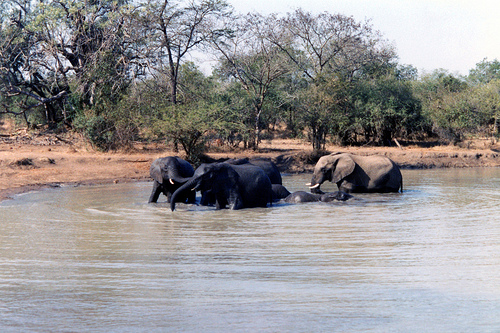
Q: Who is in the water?
A: Elephants.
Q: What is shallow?
A: Water.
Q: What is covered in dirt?
A: The ground.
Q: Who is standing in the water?
A: A elephant.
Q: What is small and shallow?
A: A pond.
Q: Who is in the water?
A: Elephants.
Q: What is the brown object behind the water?
A: Land.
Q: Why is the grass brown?
A: Dry.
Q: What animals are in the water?
A: Elephants.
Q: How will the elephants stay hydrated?
A: Water.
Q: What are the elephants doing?
A: Bathing.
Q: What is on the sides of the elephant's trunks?
A: Tusks.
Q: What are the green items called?
A: Trees.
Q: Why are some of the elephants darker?
A: Wet.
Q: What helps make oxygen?
A: Trees.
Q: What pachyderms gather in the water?
A: Elephants.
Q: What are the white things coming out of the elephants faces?
A: Tusks.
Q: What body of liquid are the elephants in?
A: Water.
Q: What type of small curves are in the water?
A: Ripples.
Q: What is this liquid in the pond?
A: Water.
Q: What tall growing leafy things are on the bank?
A: Trees.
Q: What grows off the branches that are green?
A: Leaves.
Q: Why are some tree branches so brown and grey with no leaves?
A: Dead.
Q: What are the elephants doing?
A: Playing in the water.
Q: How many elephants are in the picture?
A: Five.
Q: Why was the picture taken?
A: To capture the elephants.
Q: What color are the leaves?
A: Green.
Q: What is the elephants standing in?
A: Water.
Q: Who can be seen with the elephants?
A: No one.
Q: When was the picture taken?
A: During the day.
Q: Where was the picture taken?
A: At a watering hole.